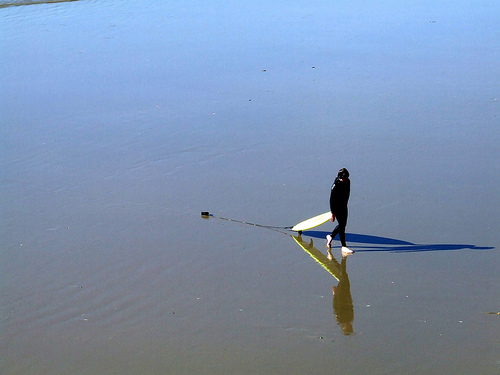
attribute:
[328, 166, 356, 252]
person — barefoot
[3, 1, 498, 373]
watered area — sandy, wet, brown sand, brown, water covered, still, bluer deeper, debris covered, edged, scattered with shell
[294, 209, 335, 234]
surfboard — yellow, being dragged, white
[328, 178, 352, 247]
wet suit — black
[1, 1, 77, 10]
land — small portion of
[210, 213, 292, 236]
rope — black, trailing behind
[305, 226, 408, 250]
shadow — cast by sun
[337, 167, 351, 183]
hair — dark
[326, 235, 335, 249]
foot — bare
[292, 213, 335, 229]
top — white